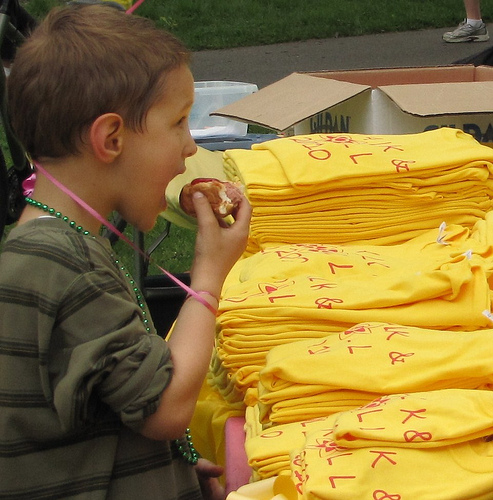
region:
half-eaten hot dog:
[177, 176, 244, 218]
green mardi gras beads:
[19, 193, 88, 238]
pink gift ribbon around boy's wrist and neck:
[23, 155, 232, 320]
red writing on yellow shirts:
[288, 134, 414, 169]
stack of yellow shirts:
[236, 127, 490, 232]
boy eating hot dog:
[0, 3, 254, 498]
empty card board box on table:
[205, 64, 492, 143]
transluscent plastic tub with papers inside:
[188, 77, 254, 139]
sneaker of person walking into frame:
[441, 3, 491, 45]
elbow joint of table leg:
[131, 224, 185, 299]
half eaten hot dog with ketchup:
[176, 177, 243, 218]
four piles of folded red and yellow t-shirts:
[248, 130, 491, 497]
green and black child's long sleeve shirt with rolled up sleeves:
[5, 223, 205, 496]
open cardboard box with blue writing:
[209, 63, 490, 133]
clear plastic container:
[191, 75, 258, 136]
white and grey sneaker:
[441, 15, 490, 45]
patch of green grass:
[197, 10, 273, 37]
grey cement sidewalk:
[252, 45, 413, 64]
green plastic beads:
[20, 195, 201, 466]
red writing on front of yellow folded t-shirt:
[297, 258, 347, 307]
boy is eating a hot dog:
[96, 70, 286, 265]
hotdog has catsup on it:
[153, 154, 269, 218]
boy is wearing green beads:
[12, 153, 194, 431]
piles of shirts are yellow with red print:
[263, 139, 468, 479]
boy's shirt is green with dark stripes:
[16, 206, 184, 482]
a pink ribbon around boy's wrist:
[44, 177, 236, 327]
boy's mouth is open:
[89, 91, 227, 233]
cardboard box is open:
[216, 47, 479, 146]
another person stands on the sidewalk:
[332, 4, 489, 82]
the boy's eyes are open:
[74, 62, 233, 168]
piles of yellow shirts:
[233, 135, 471, 494]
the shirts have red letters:
[332, 318, 424, 384]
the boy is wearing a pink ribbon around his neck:
[22, 151, 252, 323]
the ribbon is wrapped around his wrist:
[172, 268, 228, 320]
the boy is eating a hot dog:
[183, 160, 244, 236]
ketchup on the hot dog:
[180, 172, 220, 194]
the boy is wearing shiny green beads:
[11, 186, 213, 477]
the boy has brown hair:
[6, 3, 188, 191]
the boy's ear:
[84, 110, 134, 163]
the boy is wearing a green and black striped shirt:
[3, 209, 209, 497]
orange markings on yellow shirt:
[388, 404, 469, 466]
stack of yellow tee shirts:
[329, 234, 474, 370]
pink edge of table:
[219, 426, 261, 485]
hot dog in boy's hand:
[169, 163, 268, 227]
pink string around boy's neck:
[26, 162, 261, 326]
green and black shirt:
[12, 296, 149, 374]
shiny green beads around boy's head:
[45, 214, 175, 335]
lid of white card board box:
[220, 67, 401, 162]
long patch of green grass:
[188, 15, 359, 51]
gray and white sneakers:
[442, 13, 487, 51]